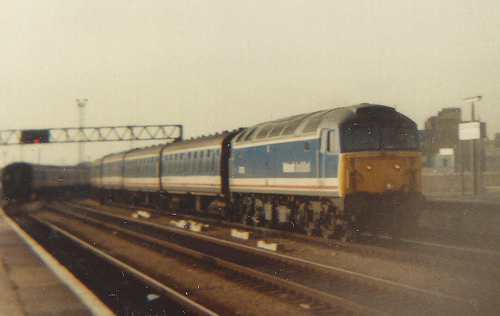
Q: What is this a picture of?
A: A train.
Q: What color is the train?
A: Blue.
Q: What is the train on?
A: Train tracks.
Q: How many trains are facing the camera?
A: One.